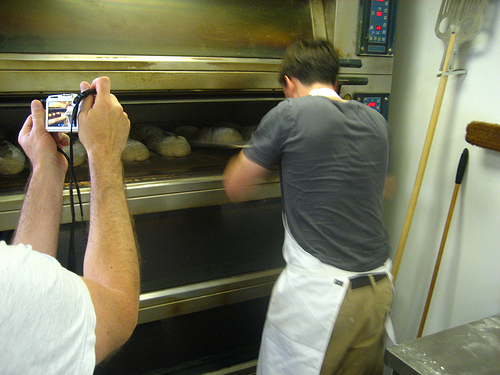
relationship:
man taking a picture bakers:
[1, 77, 140, 374] [223, 36, 397, 374]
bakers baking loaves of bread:
[223, 36, 397, 374] [196, 126, 243, 149]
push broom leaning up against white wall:
[465, 121, 499, 152] [392, 3, 498, 337]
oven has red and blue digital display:
[1, 1, 393, 375] [368, 0, 388, 53]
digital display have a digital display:
[368, 0, 388, 53] [368, 0, 388, 53]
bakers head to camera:
[278, 36, 340, 88] [45, 93, 82, 131]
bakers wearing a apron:
[223, 36, 397, 374] [256, 215, 397, 375]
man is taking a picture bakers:
[1, 77, 140, 374] [223, 36, 397, 374]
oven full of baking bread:
[1, 1, 393, 375] [0, 139, 25, 181]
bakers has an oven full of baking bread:
[223, 36, 397, 374] [137, 122, 191, 164]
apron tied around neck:
[256, 215, 397, 375] [307, 88, 342, 99]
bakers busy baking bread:
[223, 36, 397, 374] [0, 139, 25, 181]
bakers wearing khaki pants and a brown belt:
[223, 36, 397, 374] [348, 272, 392, 288]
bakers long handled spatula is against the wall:
[223, 36, 397, 374] [392, 3, 498, 337]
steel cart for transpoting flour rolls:
[385, 314, 499, 374] [196, 126, 243, 149]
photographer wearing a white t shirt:
[1, 77, 140, 374] [0, 242, 96, 375]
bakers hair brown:
[223, 36, 397, 374] [278, 36, 340, 88]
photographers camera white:
[1, 77, 140, 374] [45, 93, 82, 131]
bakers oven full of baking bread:
[223, 36, 397, 374] [0, 139, 25, 181]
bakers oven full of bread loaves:
[223, 36, 397, 374] [137, 122, 191, 164]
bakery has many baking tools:
[1, 0, 498, 374] [391, 1, 497, 373]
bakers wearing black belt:
[223, 36, 397, 374] [348, 272, 392, 288]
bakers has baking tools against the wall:
[223, 36, 397, 374] [392, 3, 498, 337]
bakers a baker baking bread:
[223, 36, 397, 374] [0, 139, 25, 181]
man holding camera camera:
[1, 77, 140, 374] [45, 93, 82, 131]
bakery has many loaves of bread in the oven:
[1, 0, 498, 374] [1, 1, 393, 375]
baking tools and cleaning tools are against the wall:
[391, 1, 497, 373] [392, 3, 498, 337]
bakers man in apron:
[223, 36, 397, 374] [256, 215, 397, 375]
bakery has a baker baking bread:
[1, 0, 498, 374] [0, 139, 25, 181]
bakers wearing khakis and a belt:
[223, 36, 397, 374] [282, 271, 394, 374]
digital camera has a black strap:
[45, 93, 82, 131] [56, 87, 96, 271]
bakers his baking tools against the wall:
[223, 36, 397, 374] [392, 3, 498, 337]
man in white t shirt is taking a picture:
[1, 77, 140, 374] [45, 93, 82, 131]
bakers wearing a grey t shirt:
[223, 36, 397, 374] [241, 97, 388, 273]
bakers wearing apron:
[223, 36, 397, 374] [256, 215, 392, 370]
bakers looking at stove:
[223, 36, 397, 374] [3, 1, 322, 373]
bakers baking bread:
[223, 36, 397, 374] [130, 120, 249, 159]